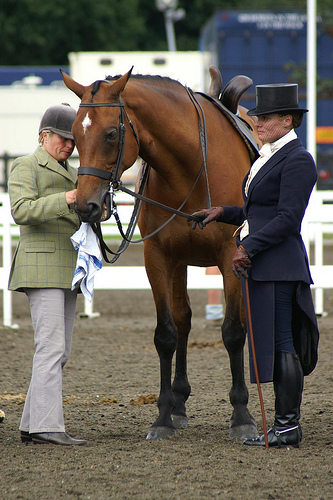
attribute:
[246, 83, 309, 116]
top hat — black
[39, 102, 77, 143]
riding cap — black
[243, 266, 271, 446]
cane — brown, long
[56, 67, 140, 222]
head — brown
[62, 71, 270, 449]
horse — brown, chestnut brown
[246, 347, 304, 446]
shoes — black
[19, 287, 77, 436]
pants — tan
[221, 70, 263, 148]
saddle — black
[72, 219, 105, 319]
towel — white, blue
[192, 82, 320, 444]
woman — dressed in blue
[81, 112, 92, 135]
spot — diamond shaped, white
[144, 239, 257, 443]
legs — black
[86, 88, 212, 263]
reins — black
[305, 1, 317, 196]
pole — white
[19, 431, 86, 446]
boots — brown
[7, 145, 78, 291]
jacket — green, blue